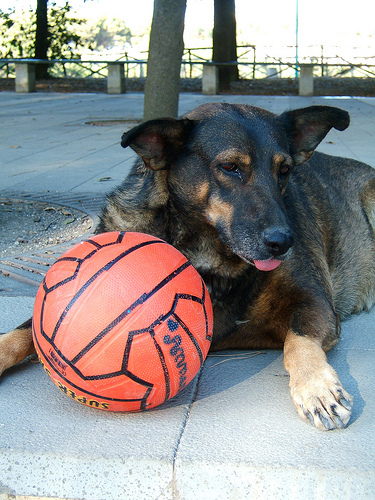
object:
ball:
[31, 229, 214, 413]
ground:
[0, 89, 375, 499]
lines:
[47, 272, 74, 294]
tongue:
[253, 258, 283, 272]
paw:
[291, 370, 356, 433]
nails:
[302, 409, 316, 427]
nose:
[264, 231, 296, 258]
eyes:
[215, 159, 244, 183]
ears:
[277, 105, 351, 168]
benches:
[0, 57, 375, 97]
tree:
[141, 0, 186, 125]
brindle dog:
[0, 100, 375, 433]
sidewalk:
[0, 88, 375, 492]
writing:
[162, 318, 189, 395]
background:
[0, 0, 374, 241]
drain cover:
[0, 190, 113, 290]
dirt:
[0, 202, 94, 256]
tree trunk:
[142, 0, 188, 121]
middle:
[131, 0, 254, 500]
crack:
[167, 350, 210, 473]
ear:
[120, 116, 191, 172]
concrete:
[0, 93, 374, 488]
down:
[0, 98, 374, 434]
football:
[25, 230, 223, 409]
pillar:
[13, 62, 36, 93]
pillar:
[106, 62, 126, 94]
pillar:
[200, 63, 220, 95]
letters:
[100, 401, 109, 411]